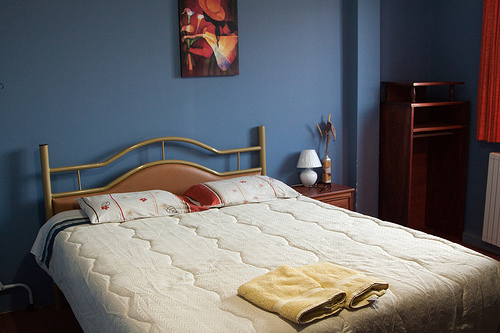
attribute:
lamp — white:
[290, 133, 330, 200]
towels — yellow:
[234, 256, 391, 332]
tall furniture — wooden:
[381, 77, 470, 244]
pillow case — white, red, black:
[187, 171, 292, 206]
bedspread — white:
[272, 202, 349, 248]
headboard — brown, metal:
[28, 121, 274, 205]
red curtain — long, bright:
[471, 4, 496, 143]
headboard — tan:
[105, 145, 196, 189]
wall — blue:
[39, 57, 107, 123]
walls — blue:
[3, 2, 495, 167]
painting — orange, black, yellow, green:
[177, 7, 237, 78]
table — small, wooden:
[294, 177, 374, 222]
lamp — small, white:
[298, 169, 318, 182]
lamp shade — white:
[293, 148, 324, 169]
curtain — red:
[474, 4, 499, 145]